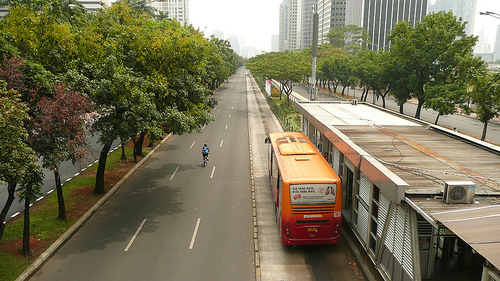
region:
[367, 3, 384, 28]
the windows of a building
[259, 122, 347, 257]
an orange passenger bus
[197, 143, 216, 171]
a person in the middle of the road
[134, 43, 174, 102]
the leaves of a tree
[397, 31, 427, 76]
the leaves of a tree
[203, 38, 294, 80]
a tree lined road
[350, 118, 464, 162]
the roof of a building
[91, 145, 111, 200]
a trunk of a tree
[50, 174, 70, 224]
the trunk of a tree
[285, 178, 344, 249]
the back of an orange bus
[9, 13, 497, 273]
Picture taken outdoors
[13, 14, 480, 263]
Picture taken during the day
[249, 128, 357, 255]
A bus is next to a bus station.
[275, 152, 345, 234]
The bus is orange and red.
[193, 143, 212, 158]
A lone bicyclists.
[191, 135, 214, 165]
The bicyclists is riding the bike.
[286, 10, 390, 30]
The tall buildings in the background.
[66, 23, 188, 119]
Tall trees lines the street.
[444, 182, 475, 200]
A HVAC unit on top of the depot.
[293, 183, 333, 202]
A white advertisement on bus.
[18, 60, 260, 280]
3 lane roadway running inside a city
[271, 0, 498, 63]
a group of towers found on a city block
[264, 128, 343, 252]
an orange bus used for public transportation parked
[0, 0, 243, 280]
row of beautiful trees planted in the median of a highway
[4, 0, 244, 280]
trees running along the stretch of a city road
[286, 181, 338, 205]
advertisement found on the back window of an orange bus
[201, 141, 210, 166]
cyclist wearing blue riding on a city block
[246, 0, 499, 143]
rows of trees in the median of a rural street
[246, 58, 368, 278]
a lane specific for public transportation via bus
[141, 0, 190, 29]
large white building seen in the background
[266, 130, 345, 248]
a parked orange bus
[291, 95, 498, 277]
an enclosed bus station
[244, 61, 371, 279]
a bus only lane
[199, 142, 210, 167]
a bicyclist on highway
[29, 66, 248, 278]
a paved three lane highway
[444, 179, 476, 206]
an air conditioning unit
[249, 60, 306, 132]
a green highway median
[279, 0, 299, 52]
a tall building in distance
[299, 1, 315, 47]
a tall building in distance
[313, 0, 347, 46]
a tall building in distance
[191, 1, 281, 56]
a cloudy and hazy sky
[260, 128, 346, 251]
a red bus parked on the side of the street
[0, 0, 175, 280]
a median filled with trees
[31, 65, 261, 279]
a street with three lanes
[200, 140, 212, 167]
a person riding a bicycle down the street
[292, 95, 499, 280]
a battered looking bus terminal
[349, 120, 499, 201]
wiring on the roof of the bus terminal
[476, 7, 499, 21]
a couple of street lights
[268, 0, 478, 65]
a series of tall buildings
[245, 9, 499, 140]
a line of trees